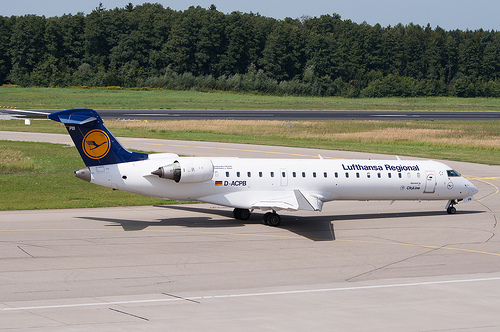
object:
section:
[117, 243, 180, 292]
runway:
[2, 210, 495, 329]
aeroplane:
[47, 106, 478, 223]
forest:
[189, 6, 223, 85]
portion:
[8, 15, 56, 88]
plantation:
[3, 3, 499, 96]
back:
[48, 109, 299, 227]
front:
[361, 158, 480, 214]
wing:
[198, 182, 328, 211]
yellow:
[93, 133, 104, 142]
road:
[173, 137, 231, 158]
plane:
[47, 109, 481, 227]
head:
[416, 160, 480, 215]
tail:
[46, 107, 148, 167]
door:
[423, 170, 438, 193]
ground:
[208, 227, 311, 289]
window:
[236, 171, 241, 178]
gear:
[258, 211, 284, 227]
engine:
[151, 158, 215, 184]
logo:
[80, 127, 111, 161]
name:
[341, 163, 420, 171]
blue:
[115, 153, 129, 160]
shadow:
[74, 216, 247, 232]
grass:
[120, 87, 159, 108]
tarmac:
[341, 290, 479, 326]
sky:
[395, 3, 499, 24]